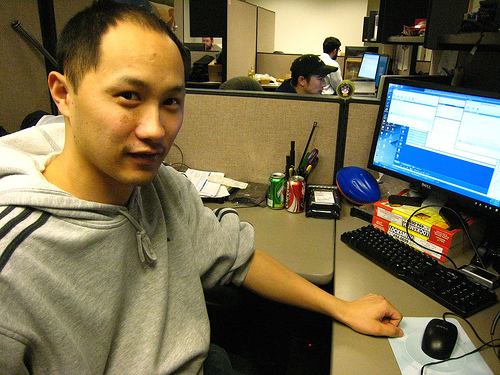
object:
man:
[0, 1, 405, 375]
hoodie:
[0, 114, 255, 375]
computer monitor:
[369, 82, 499, 210]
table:
[201, 175, 500, 374]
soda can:
[267, 172, 287, 210]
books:
[372, 185, 488, 263]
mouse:
[422, 318, 459, 360]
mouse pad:
[384, 316, 494, 374]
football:
[336, 166, 381, 205]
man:
[274, 54, 339, 95]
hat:
[290, 54, 339, 78]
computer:
[377, 75, 453, 106]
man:
[319, 36, 348, 93]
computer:
[374, 54, 390, 89]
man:
[201, 37, 222, 54]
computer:
[180, 43, 207, 51]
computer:
[368, 77, 500, 243]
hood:
[0, 115, 167, 218]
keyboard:
[341, 224, 498, 319]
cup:
[286, 175, 307, 213]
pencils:
[298, 121, 318, 168]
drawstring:
[119, 193, 157, 264]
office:
[0, 0, 499, 373]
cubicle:
[1, 75, 498, 374]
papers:
[207, 174, 248, 190]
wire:
[441, 306, 500, 352]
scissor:
[304, 148, 319, 171]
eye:
[113, 89, 143, 101]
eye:
[162, 97, 180, 106]